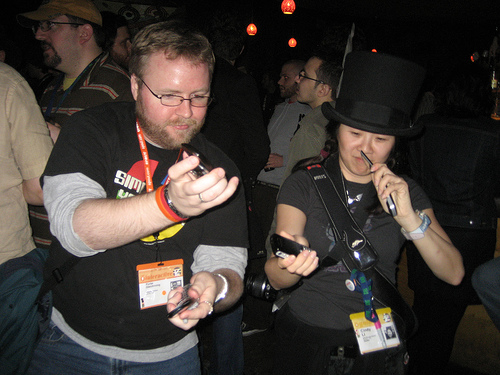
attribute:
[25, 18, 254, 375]
man — standing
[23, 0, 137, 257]
man — standing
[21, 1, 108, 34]
cap — yellow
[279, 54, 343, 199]
man — standing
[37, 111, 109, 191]
sleeve — short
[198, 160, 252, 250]
sleeve — short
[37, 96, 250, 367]
shirt — black, gray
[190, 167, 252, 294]
sleeve — long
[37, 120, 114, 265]
sleeve — long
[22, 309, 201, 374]
jeans — blue